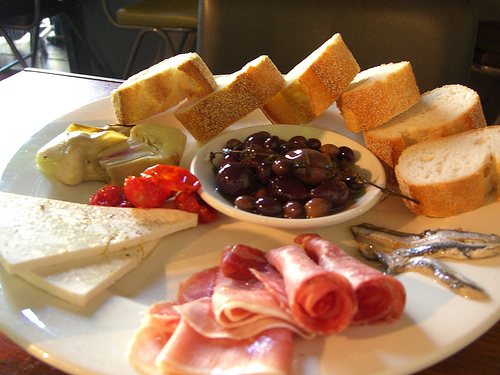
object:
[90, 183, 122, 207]
tomatoes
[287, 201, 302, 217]
olive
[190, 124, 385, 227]
dish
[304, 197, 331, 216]
olive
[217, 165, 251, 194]
olive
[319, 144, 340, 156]
olive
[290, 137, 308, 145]
olive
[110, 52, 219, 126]
slice of bread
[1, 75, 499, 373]
dish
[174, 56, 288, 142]
slice of bread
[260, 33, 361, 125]
slice of bread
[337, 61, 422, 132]
slice of bread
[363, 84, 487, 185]
slice of bread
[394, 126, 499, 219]
slice of bread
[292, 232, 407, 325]
meat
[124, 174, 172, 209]
fruit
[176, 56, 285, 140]
crust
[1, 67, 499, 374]
table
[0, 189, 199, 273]
cheese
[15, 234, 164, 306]
cheese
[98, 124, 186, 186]
mushroom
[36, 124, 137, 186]
mushroom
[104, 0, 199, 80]
chair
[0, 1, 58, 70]
chair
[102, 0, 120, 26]
back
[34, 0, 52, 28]
back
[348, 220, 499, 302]
sardines